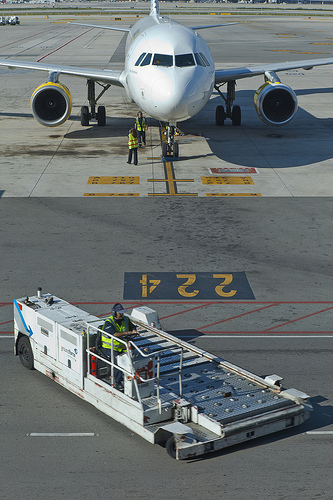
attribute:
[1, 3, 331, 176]
plane — large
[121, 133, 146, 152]
vest — yellow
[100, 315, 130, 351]
vest — bright colored, safety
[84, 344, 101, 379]
fire extinguisher — red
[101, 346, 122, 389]
jeans — blue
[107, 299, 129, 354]
male — worker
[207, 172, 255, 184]
numbers — yellow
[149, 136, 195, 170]
wheel — black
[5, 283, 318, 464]
vehicle — white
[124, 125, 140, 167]
female — airport personnel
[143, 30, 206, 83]
cockpit — white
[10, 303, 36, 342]
arrow — blue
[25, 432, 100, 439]
line — white, dotted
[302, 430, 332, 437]
line — white, dotted